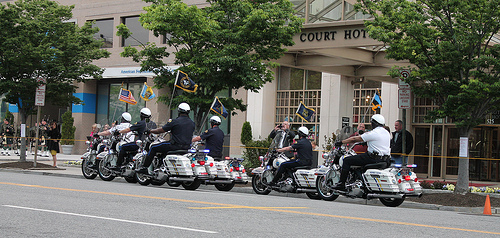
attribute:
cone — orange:
[475, 190, 495, 230]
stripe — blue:
[1, 86, 96, 116]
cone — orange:
[471, 179, 484, 219]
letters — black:
[298, 26, 370, 44]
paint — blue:
[70, 90, 95, 113]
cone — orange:
[477, 193, 484, 221]